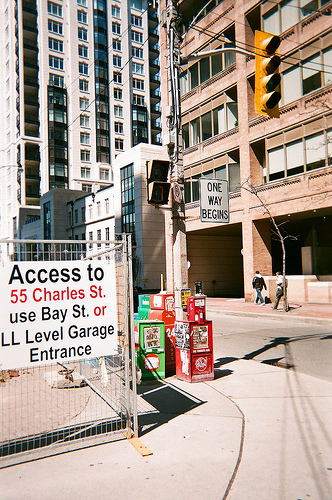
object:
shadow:
[121, 379, 207, 440]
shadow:
[209, 336, 292, 368]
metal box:
[175, 320, 212, 355]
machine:
[149, 274, 178, 376]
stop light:
[262, 69, 282, 92]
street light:
[261, 52, 281, 76]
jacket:
[251, 274, 268, 291]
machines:
[135, 289, 153, 323]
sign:
[0, 257, 119, 372]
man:
[269, 271, 288, 312]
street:
[205, 298, 330, 379]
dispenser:
[181, 291, 208, 323]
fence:
[0, 363, 138, 443]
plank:
[124, 430, 152, 455]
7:
[158, 185, 163, 202]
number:
[10, 288, 19, 305]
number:
[152, 184, 168, 203]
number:
[166, 328, 171, 338]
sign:
[200, 178, 229, 222]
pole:
[166, 17, 189, 317]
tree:
[244, 166, 299, 317]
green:
[141, 353, 166, 383]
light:
[149, 161, 170, 183]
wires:
[173, 20, 321, 65]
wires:
[1, 22, 162, 177]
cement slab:
[0, 374, 160, 441]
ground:
[142, 412, 329, 496]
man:
[250, 268, 267, 307]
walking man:
[273, 271, 289, 311]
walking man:
[252, 269, 269, 306]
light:
[261, 85, 281, 113]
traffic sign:
[199, 176, 229, 223]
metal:
[190, 328, 207, 350]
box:
[174, 346, 215, 386]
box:
[133, 350, 165, 381]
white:
[220, 182, 227, 206]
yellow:
[253, 77, 266, 95]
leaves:
[259, 214, 265, 219]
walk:
[142, 164, 178, 253]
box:
[147, 178, 172, 206]